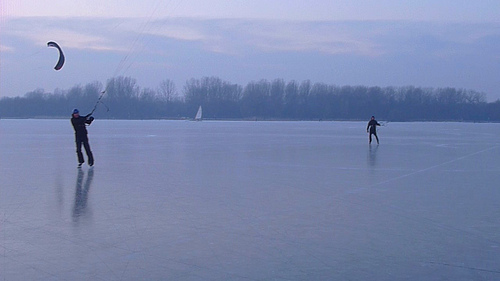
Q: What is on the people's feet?
A: Skates.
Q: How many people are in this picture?
A: Two.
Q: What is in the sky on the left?
A: A kite.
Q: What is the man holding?
A: A kite.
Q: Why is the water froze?
A: It's cold.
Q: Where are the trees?
A: The background.